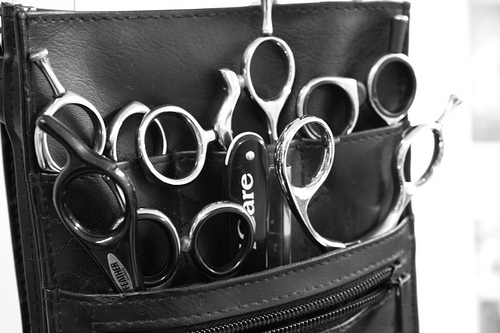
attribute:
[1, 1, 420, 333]
holder — black, leather, open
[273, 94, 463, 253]
scissors — shiny, spread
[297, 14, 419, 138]
scissors — shiny, grey, silver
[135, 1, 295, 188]
scissors — shiny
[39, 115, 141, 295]
scissors — black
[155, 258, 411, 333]
zipper — black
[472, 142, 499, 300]
object — white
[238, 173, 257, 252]
text — white, silver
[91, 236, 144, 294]
handle — black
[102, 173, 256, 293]
scissors — silver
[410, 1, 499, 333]
background — blurry